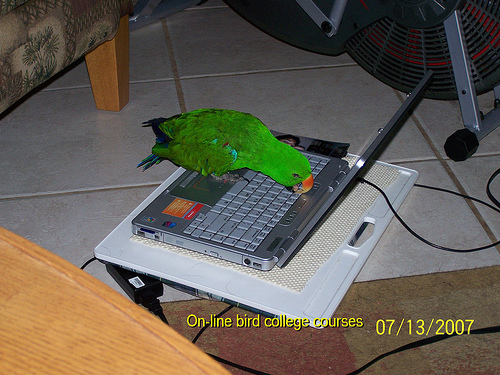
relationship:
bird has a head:
[135, 108, 316, 196] [269, 133, 319, 204]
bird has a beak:
[135, 108, 316, 196] [288, 177, 317, 192]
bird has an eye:
[135, 108, 316, 196] [291, 172, 304, 180]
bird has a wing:
[135, 108, 316, 196] [149, 139, 234, 175]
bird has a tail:
[135, 108, 316, 196] [142, 113, 187, 133]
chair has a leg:
[3, 3, 137, 129] [86, 22, 134, 115]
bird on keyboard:
[135, 108, 316, 196] [194, 164, 291, 260]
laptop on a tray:
[133, 62, 429, 273] [98, 234, 379, 310]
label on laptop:
[167, 198, 208, 225] [133, 62, 429, 273]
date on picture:
[376, 316, 477, 338] [2, 2, 500, 373]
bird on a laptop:
[135, 108, 316, 196] [133, 62, 429, 273]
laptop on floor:
[133, 62, 429, 273] [28, 1, 500, 372]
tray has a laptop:
[98, 234, 379, 310] [133, 62, 429, 273]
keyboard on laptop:
[194, 164, 291, 260] [133, 62, 429, 273]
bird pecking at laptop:
[135, 108, 316, 196] [133, 62, 429, 273]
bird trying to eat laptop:
[135, 108, 316, 196] [133, 62, 429, 273]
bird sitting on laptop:
[135, 108, 316, 196] [133, 62, 429, 273]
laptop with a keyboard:
[133, 62, 429, 273] [194, 164, 291, 260]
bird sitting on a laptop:
[135, 108, 316, 196] [133, 62, 429, 273]